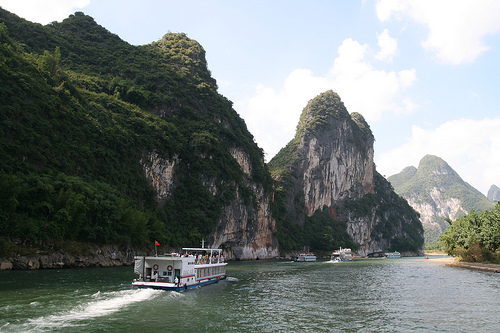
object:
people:
[181, 252, 186, 258]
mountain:
[97, 32, 283, 267]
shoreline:
[0, 256, 291, 274]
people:
[197, 252, 205, 265]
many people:
[219, 251, 226, 263]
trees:
[433, 208, 500, 262]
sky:
[0, 3, 498, 163]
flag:
[154, 240, 162, 258]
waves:
[0, 281, 174, 329]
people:
[204, 253, 208, 265]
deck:
[177, 247, 231, 270]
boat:
[129, 236, 227, 296]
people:
[188, 252, 194, 265]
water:
[0, 254, 500, 326]